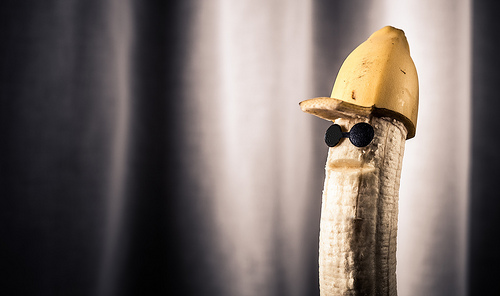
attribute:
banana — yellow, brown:
[308, 23, 411, 293]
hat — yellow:
[315, 14, 415, 124]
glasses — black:
[321, 114, 370, 149]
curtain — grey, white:
[123, 29, 191, 74]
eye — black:
[322, 120, 340, 145]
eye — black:
[347, 125, 380, 144]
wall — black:
[471, 13, 493, 276]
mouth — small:
[319, 154, 369, 174]